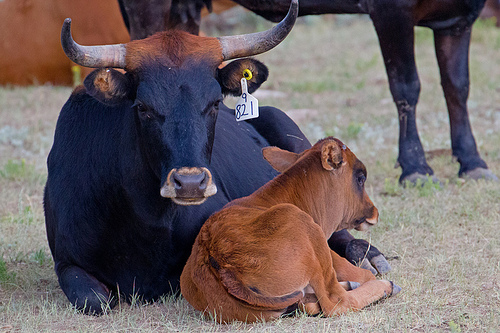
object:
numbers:
[238, 103, 248, 117]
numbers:
[248, 99, 256, 116]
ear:
[219, 58, 268, 99]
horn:
[58, 19, 126, 69]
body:
[178, 195, 402, 314]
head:
[58, 1, 298, 206]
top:
[124, 29, 224, 75]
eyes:
[128, 104, 158, 124]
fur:
[130, 38, 214, 80]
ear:
[317, 142, 342, 172]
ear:
[261, 147, 297, 173]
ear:
[82, 67, 137, 109]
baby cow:
[179, 136, 402, 326]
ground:
[0, 6, 499, 333]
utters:
[171, 0, 216, 27]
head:
[259, 137, 377, 231]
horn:
[217, 0, 301, 62]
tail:
[206, 255, 306, 311]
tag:
[234, 78, 259, 122]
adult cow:
[41, 0, 388, 318]